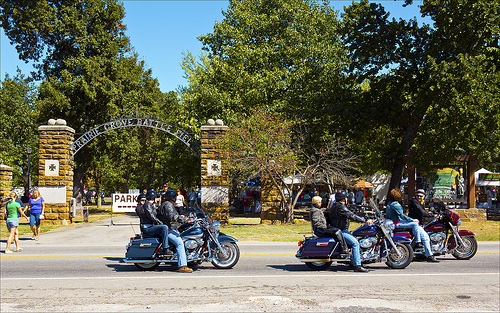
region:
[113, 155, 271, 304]
a hot looking bike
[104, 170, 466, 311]
three group of bikes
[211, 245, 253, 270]
front wheel of the bike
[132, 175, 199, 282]
two person sitting in the bike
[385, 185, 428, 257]
a young lady sitting in the bike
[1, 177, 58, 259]
two young girls walking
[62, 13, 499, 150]
a large group of trees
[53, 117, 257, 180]
a small entrance on top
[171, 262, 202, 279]
shoe of the person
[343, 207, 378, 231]
hand of the person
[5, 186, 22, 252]
Girl in a green shirt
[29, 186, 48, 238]
Woman in a blue shirt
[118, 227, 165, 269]
Blue saddlebag on a motorcycle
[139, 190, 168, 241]
Woman on the back of a motorcycle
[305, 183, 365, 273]
Man and woman on a motorcyle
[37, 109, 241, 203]
Entry way into a park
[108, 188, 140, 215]
Parking sign at a park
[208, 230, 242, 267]
front wheel of a motorcycle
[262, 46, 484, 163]
Trees at a park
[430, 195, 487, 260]
front end of a red motorcycle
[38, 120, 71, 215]
a brick column of a entrance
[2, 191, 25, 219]
a woman wearing a green shirt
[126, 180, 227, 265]
two people on a motorcycle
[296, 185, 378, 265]
two people on a motorcycle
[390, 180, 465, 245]
two people on a motorcycle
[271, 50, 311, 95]
the leaves of a tree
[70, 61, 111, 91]
the leaves of a tree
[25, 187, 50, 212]
a woman a wearing blue shirt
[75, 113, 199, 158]
a sign over an entrance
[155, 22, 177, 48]
the clear blue sky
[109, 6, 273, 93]
the sky is blue and clear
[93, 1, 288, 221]
the sky is blue and clear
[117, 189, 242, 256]
Two people ride motorcycle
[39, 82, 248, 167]
The park has a sign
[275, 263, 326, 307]
The road is stained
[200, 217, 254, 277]
The front wheel of the motorcycle is black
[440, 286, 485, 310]
Grease stain on the road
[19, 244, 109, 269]
Yellow paint on the road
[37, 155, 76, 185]
sign on the stone column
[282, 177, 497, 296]
Two motorcycles ride together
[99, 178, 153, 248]
A sign for parking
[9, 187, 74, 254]
Two women walk toward each other